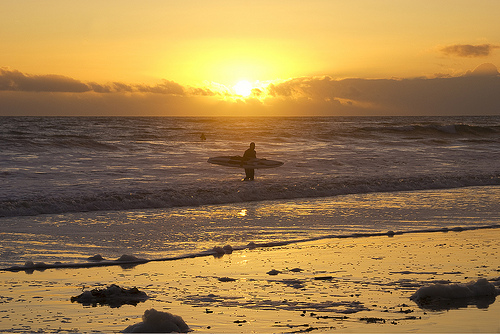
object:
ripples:
[262, 122, 338, 146]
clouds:
[0, 43, 499, 117]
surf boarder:
[0, 165, 499, 215]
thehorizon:
[6, 4, 496, 117]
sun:
[167, 52, 284, 97]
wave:
[332, 168, 387, 195]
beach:
[0, 181, 499, 333]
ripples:
[0, 174, 61, 206]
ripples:
[422, 120, 489, 147]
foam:
[0, 224, 499, 271]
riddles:
[0, 161, 500, 217]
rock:
[71, 285, 148, 311]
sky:
[0, 0, 499, 122]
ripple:
[144, 164, 224, 171]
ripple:
[96, 169, 183, 181]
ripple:
[60, 145, 209, 157]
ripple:
[267, 169, 363, 178]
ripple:
[288, 148, 377, 165]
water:
[0, 113, 499, 334]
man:
[244, 142, 256, 181]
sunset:
[148, 50, 354, 123]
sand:
[55, 209, 491, 330]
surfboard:
[207, 155, 284, 170]